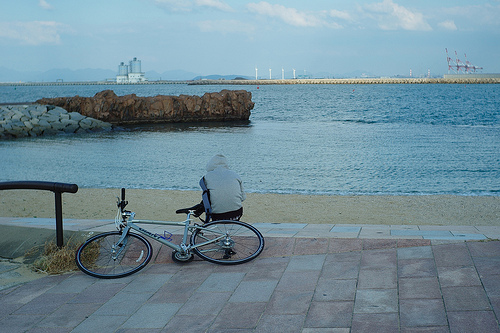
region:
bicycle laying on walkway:
[60, 178, 260, 280]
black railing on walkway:
[6, 176, 81, 244]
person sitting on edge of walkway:
[168, 149, 253, 224]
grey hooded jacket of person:
[196, 146, 249, 216]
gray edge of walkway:
[3, 223, 498, 237]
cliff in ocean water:
[73, 81, 253, 123]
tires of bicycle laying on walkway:
[72, 221, 258, 277]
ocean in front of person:
[14, 82, 484, 174]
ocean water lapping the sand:
[24, 158, 489, 200]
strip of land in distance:
[194, 76, 497, 96]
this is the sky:
[286, 17, 408, 54]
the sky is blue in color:
[268, 45, 320, 68]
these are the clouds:
[262, 9, 299, 26]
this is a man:
[203, 152, 239, 222]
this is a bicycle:
[70, 212, 253, 267]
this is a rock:
[126, 95, 186, 114]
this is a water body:
[297, 95, 479, 179]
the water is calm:
[315, 101, 462, 169]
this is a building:
[109, 60, 153, 79]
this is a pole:
[277, 69, 293, 78]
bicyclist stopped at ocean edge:
[10, 3, 491, 288]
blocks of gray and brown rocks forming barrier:
[2, 82, 253, 137]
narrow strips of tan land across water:
[5, 75, 495, 87]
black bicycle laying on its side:
[70, 171, 265, 276]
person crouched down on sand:
[175, 150, 245, 220]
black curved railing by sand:
[2, 171, 77, 251]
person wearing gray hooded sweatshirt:
[177, 145, 243, 220]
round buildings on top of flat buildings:
[111, 55, 141, 85]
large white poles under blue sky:
[187, 3, 346, 80]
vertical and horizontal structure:
[441, 42, 481, 73]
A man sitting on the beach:
[173, 150, 265, 225]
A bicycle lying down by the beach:
[76, 190, 270, 283]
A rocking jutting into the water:
[0, 85, 260, 144]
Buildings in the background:
[103, 50, 149, 85]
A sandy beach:
[1, 179, 498, 229]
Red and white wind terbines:
[431, 38, 489, 88]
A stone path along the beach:
[2, 239, 498, 331]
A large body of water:
[1, 83, 498, 195]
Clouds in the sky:
[0, 2, 460, 42]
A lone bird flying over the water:
[252, 83, 262, 92]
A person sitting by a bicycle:
[188, 153, 239, 225]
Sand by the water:
[3, 188, 497, 217]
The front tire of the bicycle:
[79, 227, 147, 275]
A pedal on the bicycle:
[173, 240, 191, 252]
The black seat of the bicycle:
[174, 205, 206, 216]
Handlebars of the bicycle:
[115, 188, 132, 218]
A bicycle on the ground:
[78, 190, 272, 275]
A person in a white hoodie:
[199, 157, 247, 219]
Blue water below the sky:
[4, 80, 496, 180]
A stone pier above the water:
[0, 91, 252, 136]